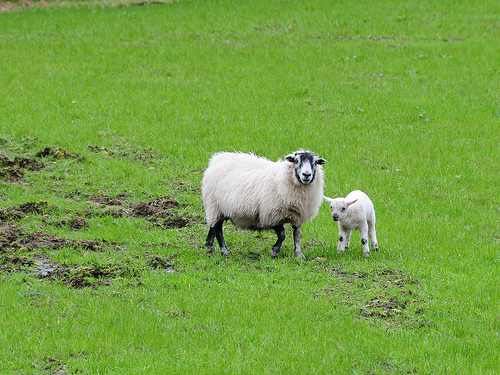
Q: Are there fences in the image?
A: No, there are no fences.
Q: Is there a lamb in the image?
A: Yes, there is a lamb.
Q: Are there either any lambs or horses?
A: Yes, there is a lamb.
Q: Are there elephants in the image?
A: No, there are no elephants.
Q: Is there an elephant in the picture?
A: No, there are no elephants.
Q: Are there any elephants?
A: No, there are no elephants.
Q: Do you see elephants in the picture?
A: No, there are no elephants.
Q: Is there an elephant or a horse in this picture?
A: No, there are no elephants or horses.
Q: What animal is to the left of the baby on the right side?
A: The animal is a lamb.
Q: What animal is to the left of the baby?
A: The animal is a lamb.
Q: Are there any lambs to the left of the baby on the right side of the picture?
A: Yes, there is a lamb to the left of the baby.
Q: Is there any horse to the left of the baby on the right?
A: No, there is a lamb to the left of the baby.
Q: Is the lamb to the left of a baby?
A: Yes, the lamb is to the left of a baby.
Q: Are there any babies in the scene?
A: Yes, there is a baby.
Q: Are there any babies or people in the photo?
A: Yes, there is a baby.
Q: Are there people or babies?
A: Yes, there is a baby.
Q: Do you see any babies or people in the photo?
A: Yes, there is a baby.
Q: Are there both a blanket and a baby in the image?
A: No, there is a baby but no blankets.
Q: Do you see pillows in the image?
A: No, there are no pillows.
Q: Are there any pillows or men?
A: No, there are no pillows or men.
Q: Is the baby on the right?
A: Yes, the baby is on the right of the image.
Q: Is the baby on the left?
A: No, the baby is on the right of the image.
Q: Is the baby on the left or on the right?
A: The baby is on the right of the image.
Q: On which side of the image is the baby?
A: The baby is on the right of the image.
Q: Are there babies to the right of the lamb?
A: Yes, there is a baby to the right of the lamb.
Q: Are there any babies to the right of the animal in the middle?
A: Yes, there is a baby to the right of the lamb.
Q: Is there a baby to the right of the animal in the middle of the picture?
A: Yes, there is a baby to the right of the lamb.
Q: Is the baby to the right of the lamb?
A: Yes, the baby is to the right of the lamb.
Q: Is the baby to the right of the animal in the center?
A: Yes, the baby is to the right of the lamb.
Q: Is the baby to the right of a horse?
A: No, the baby is to the right of the lamb.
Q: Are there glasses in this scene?
A: No, there are no glasses.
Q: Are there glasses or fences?
A: No, there are no glasses or fences.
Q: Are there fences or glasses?
A: No, there are no glasses or fences.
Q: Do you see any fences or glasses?
A: No, there are no glasses or fences.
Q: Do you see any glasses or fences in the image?
A: No, there are no glasses or fences.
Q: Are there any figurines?
A: No, there are no figurines.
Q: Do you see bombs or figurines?
A: No, there are no figurines or bombs.